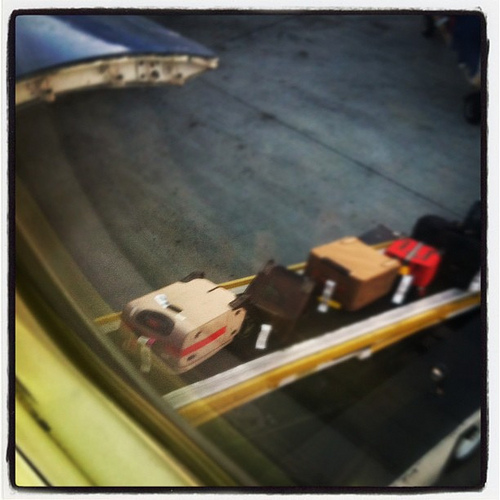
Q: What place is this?
A: It is a pavement.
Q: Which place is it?
A: It is a pavement.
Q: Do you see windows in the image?
A: Yes, there is a window.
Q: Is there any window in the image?
A: Yes, there is a window.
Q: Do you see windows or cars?
A: Yes, there is a window.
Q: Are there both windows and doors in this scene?
A: Yes, there are both a window and a door.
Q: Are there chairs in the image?
A: No, there are no chairs.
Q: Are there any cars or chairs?
A: No, there are no chairs or cars.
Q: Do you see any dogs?
A: No, there are no dogs.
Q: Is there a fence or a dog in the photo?
A: No, there are no dogs or fences.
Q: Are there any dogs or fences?
A: No, there are no dogs or fences.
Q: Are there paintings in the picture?
A: No, there are no paintings.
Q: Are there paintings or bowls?
A: No, there are no paintings or bowls.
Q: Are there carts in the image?
A: No, there are no carts.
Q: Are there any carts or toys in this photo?
A: No, there are no carts or toys.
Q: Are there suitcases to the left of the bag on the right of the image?
A: Yes, there is a suitcase to the left of the bag.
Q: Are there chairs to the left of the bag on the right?
A: No, there is a suitcase to the left of the bag.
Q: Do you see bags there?
A: Yes, there is a bag.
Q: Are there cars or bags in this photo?
A: Yes, there is a bag.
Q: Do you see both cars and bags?
A: No, there is a bag but no cars.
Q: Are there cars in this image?
A: No, there are no cars.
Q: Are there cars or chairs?
A: No, there are no cars or chairs.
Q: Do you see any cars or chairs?
A: No, there are no cars or chairs.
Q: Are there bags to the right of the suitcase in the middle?
A: Yes, there is a bag to the right of the suitcase.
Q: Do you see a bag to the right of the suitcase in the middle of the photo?
A: Yes, there is a bag to the right of the suitcase.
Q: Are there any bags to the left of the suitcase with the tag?
A: No, the bag is to the right of the suitcase.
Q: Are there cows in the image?
A: No, there are no cows.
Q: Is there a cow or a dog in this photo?
A: No, there are no cows or dogs.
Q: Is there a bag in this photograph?
A: Yes, there is a bag.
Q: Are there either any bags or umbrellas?
A: Yes, there is a bag.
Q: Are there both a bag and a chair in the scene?
A: No, there is a bag but no chairs.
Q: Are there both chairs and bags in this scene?
A: No, there is a bag but no chairs.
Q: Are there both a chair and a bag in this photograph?
A: No, there is a bag but no chairs.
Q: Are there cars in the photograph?
A: No, there are no cars.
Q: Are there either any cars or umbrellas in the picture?
A: No, there are no cars or umbrellas.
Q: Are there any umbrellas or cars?
A: No, there are no cars or umbrellas.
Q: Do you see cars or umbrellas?
A: No, there are no cars or umbrellas.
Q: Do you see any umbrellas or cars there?
A: No, there are no cars or umbrellas.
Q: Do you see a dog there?
A: No, there are no dogs.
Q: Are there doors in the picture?
A: Yes, there is a door.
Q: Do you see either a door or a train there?
A: Yes, there is a door.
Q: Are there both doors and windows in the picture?
A: Yes, there are both a door and a window.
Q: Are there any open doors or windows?
A: Yes, there is an open door.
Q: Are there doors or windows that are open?
A: Yes, the door is open.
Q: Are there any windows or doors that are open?
A: Yes, the door is open.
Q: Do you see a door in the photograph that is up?
A: Yes, there is a door that is up.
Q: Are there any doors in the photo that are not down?
A: Yes, there is a door that is up.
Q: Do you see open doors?
A: Yes, there is an open door.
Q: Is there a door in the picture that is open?
A: Yes, there is a door that is open.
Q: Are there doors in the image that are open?
A: Yes, there is a door that is open.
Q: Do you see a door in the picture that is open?
A: Yes, there is a door that is open.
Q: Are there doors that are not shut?
A: Yes, there is a open door.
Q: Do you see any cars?
A: No, there are no cars.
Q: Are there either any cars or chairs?
A: No, there are no cars or chairs.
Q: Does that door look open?
A: Yes, the door is open.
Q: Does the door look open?
A: Yes, the door is open.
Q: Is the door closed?
A: No, the door is open.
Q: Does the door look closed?
A: No, the door is open.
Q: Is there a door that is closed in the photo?
A: No, there is a door but it is open.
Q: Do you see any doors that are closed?
A: No, there is a door but it is open.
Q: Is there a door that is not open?
A: No, there is a door but it is open.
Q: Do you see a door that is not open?
A: No, there is a door but it is open.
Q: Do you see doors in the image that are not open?
A: No, there is a door but it is open.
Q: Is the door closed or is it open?
A: The door is open.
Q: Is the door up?
A: Yes, the door is up.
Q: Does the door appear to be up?
A: Yes, the door is up.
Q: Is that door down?
A: No, the door is up.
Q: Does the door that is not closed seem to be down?
A: No, the door is up.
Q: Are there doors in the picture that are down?
A: No, there is a door but it is up.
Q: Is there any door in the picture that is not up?
A: No, there is a door but it is up.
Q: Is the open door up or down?
A: The door is up.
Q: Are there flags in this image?
A: No, there are no flags.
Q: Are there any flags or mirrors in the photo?
A: No, there are no flags or mirrors.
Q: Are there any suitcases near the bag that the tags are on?
A: Yes, there is a suitcase near the bag.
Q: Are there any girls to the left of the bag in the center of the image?
A: No, there is a suitcase to the left of the bag.